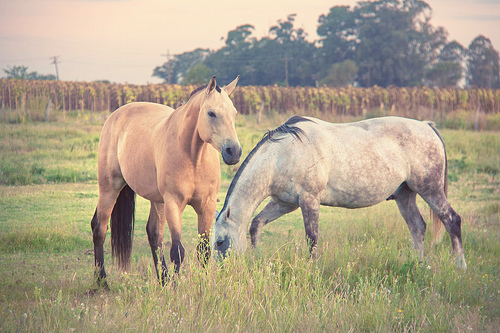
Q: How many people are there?
A: 0.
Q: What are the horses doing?
A: Grazing.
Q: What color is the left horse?
A: Brown.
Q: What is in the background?
A: Corn.